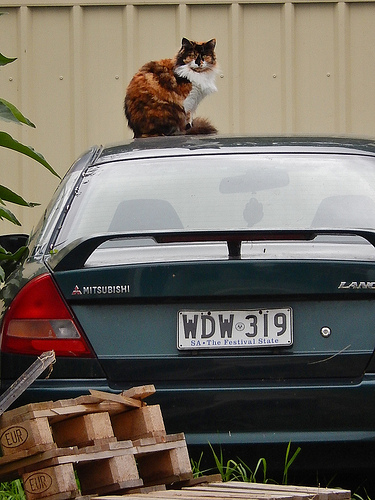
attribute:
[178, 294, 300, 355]
license plate — white, festival state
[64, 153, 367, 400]
car — green, blue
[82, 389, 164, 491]
wood — brown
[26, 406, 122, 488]
blocks — wood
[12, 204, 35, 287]
grass — green, standing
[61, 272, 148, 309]
logo — mitsubishi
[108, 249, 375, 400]
trunk — mitsubishi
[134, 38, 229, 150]
cat — brown, fluffy, sitting, black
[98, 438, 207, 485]
pallet — wood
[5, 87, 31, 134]
leaf — green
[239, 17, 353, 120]
wall — metal, tan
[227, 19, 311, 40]
metal — lenth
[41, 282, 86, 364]
taillight — three lens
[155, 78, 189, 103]
fur — fuzzy